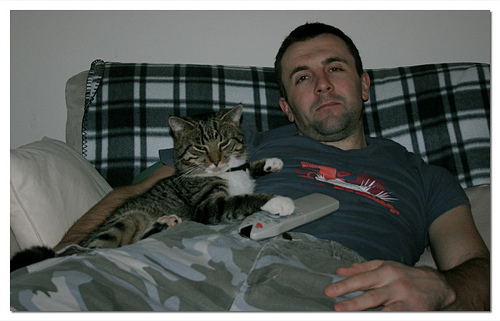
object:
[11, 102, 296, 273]
cat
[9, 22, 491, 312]
man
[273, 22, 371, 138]
head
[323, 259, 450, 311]
hand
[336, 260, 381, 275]
finger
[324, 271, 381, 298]
finger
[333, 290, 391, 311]
finger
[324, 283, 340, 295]
finger nail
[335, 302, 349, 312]
finger nail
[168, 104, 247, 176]
head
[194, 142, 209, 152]
eye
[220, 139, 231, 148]
eye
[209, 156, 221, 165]
nose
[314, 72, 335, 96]
nose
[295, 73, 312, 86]
eye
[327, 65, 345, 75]
eye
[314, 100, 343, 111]
mouth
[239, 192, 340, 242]
remote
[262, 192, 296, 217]
paw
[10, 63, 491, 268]
couch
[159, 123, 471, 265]
shirt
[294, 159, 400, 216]
design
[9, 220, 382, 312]
pants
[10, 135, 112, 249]
pillow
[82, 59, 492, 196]
blanket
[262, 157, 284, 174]
paw